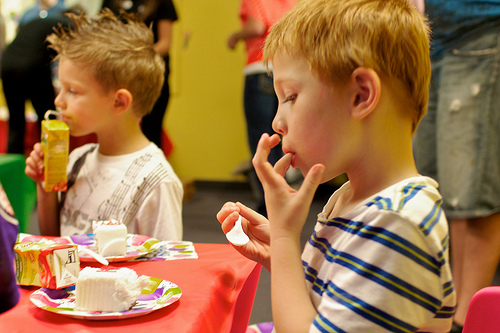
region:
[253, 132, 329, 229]
a hand of a child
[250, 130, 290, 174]
the fingers of a hand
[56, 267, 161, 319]
white cake with frosting on a paper plate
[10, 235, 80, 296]
an empty juice box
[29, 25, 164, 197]
a boy drinking a juice box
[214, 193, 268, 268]
a hand holding a white plastic spoon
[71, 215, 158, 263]
white cake with frosting on a paper plate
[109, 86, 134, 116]
the ear of a child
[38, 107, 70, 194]
a juice box with a straw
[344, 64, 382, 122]
the ear of a child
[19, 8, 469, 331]
a couple of kids are eating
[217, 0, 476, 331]
a kid with striped shirt eating a cake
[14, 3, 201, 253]
a kid drinking a juice box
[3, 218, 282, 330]
a red tablecloth on a table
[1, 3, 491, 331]
a scene of a party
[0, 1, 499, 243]
some people in the background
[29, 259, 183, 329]
a white cake on a plate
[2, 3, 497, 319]
a scene indoors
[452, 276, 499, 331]
a red chair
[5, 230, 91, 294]
a discarded juice box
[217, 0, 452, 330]
this is a boy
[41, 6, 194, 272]
this is a boy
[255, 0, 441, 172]
the boy has blonde hair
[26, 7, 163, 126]
the boy has blonde hair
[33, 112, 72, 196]
this is a packet of juice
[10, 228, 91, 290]
this is a packet of juice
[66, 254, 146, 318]
this is a cake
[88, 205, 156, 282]
this is a cake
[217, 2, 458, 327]
a little boy eating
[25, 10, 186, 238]
a little boy drinking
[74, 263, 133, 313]
a piece of cake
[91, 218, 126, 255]
a piece of cake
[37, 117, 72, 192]
a yellow juice box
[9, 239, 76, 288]
a yellow juice box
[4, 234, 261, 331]
a red table cloth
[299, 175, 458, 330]
a blue and white striped shirt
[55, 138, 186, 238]
a white printed t-shirt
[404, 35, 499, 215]
a pair of blue jean shorts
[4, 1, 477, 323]
Boys are at a birthday party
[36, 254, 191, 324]
The cake is on a paper plate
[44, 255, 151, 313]
The cake has white frosting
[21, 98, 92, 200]
The boy is drinking juice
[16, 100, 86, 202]
The juice is in a box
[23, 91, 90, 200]
The juice box is yellow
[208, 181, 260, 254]
The plastic spoon is white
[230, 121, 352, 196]
The boy is licking his finger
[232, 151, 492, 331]
The boys shirt has blue stripes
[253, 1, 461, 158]
The boy has blonde hair